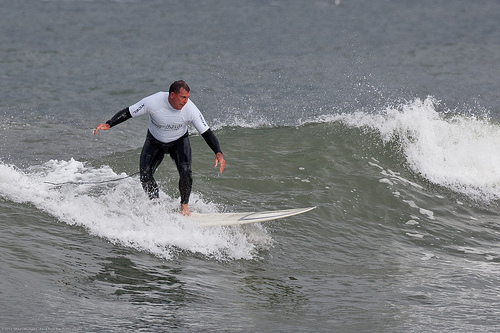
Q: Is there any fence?
A: No, there are no fences.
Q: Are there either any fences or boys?
A: No, there are no fences or boys.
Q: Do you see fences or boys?
A: No, there are no fences or boys.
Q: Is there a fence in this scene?
A: No, there are no fences.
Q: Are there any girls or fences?
A: No, there are no fences or girls.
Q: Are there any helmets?
A: No, there are no helmets.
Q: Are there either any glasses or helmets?
A: No, there are no helmets or glasses.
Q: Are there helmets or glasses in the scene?
A: No, there are no helmets or glasses.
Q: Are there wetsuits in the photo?
A: Yes, there is a wetsuit.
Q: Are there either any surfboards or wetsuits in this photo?
A: Yes, there is a wetsuit.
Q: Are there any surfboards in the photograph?
A: Yes, there is a surfboard.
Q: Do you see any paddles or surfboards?
A: Yes, there is a surfboard.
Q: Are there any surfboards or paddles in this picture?
A: Yes, there is a surfboard.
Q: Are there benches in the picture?
A: No, there are no benches.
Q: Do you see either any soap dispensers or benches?
A: No, there are no benches or soap dispensers.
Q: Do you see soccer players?
A: No, there are no soccer players.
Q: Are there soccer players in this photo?
A: No, there are no soccer players.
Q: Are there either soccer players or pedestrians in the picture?
A: No, there are no soccer players or pedestrians.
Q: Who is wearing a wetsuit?
A: The man is wearing a wetsuit.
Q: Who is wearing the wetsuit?
A: The man is wearing a wetsuit.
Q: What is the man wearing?
A: The man is wearing a wetsuit.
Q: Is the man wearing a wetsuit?
A: Yes, the man is wearing a wetsuit.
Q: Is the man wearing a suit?
A: No, the man is wearing a wetsuit.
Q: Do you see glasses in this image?
A: No, there are no glasses.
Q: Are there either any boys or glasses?
A: No, there are no glasses or boys.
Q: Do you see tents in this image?
A: No, there are no tents.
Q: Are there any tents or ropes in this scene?
A: No, there are no tents or ropes.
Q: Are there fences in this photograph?
A: No, there are no fences.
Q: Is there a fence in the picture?
A: No, there are no fences.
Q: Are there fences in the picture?
A: No, there are no fences.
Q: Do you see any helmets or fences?
A: No, there are no fences or helmets.